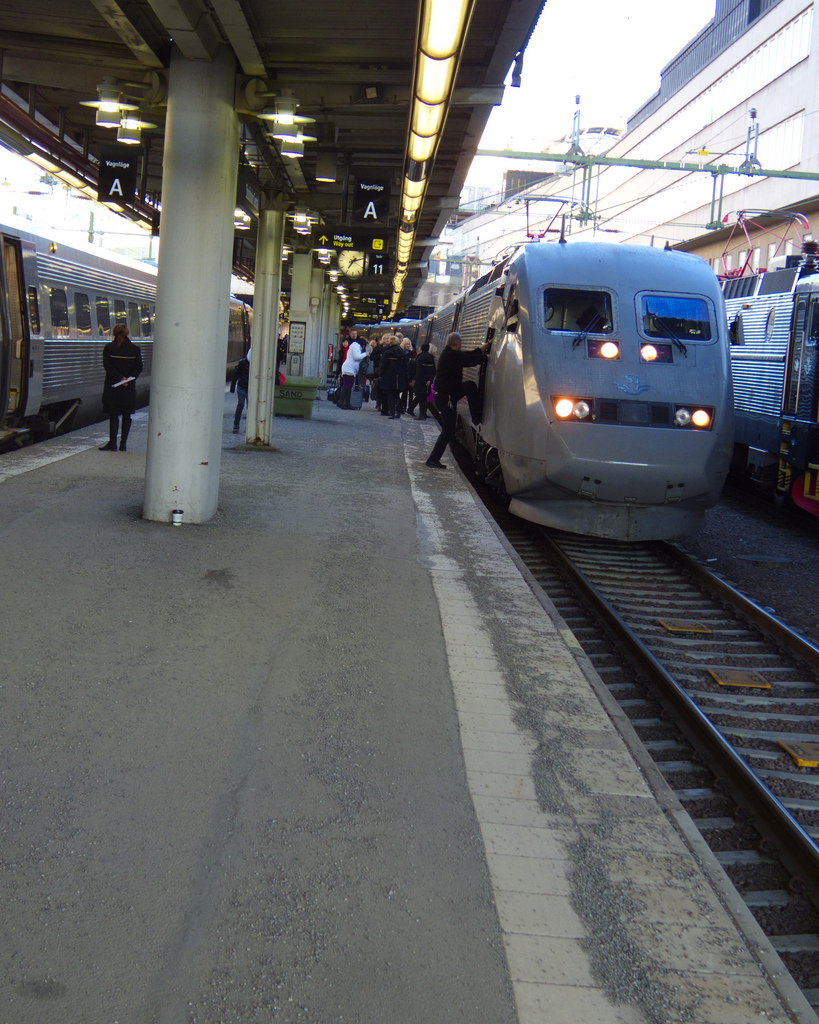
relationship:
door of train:
[462, 263, 526, 451] [2, 235, 362, 467]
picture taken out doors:
[67, 64, 720, 762] [492, 47, 752, 742]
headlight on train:
[599, 339, 619, 362] [346, 238, 737, 546]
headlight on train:
[643, 344, 657, 361] [346, 238, 737, 546]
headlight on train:
[556, 399, 573, 416] [346, 238, 737, 546]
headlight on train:
[574, 402, 590, 418] [346, 238, 737, 546]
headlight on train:
[675, 406, 689, 428] [346, 238, 737, 546]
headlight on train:
[695, 408, 709, 424] [346, 238, 737, 546]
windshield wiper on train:
[571, 290, 614, 349] [346, 238, 737, 546]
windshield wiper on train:
[643, 302, 693, 357] [346, 238, 737, 546]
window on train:
[538, 267, 619, 344] [346, 238, 737, 546]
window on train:
[640, 289, 714, 342] [346, 238, 737, 546]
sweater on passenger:
[342, 339, 371, 376] [333, 327, 370, 408]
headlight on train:
[592, 331, 626, 369] [346, 238, 737, 546]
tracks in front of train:
[525, 533, 816, 1018] [346, 238, 737, 546]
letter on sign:
[358, 198, 377, 226] [340, 164, 395, 239]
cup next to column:
[165, 506, 188, 531] [124, 61, 232, 527]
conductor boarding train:
[409, 314, 493, 475] [419, 232, 718, 550]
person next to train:
[103, 314, 149, 455] [6, 221, 254, 436]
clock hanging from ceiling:
[332, 247, 376, 278] [6, 68, 473, 343]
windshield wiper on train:
[571, 290, 622, 363] [402, 233, 738, 557]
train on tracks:
[387, 247, 723, 564] [521, 528, 793, 886]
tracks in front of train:
[527, 537, 793, 995] [365, 226, 719, 578]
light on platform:
[389, 162, 423, 316] [8, 1, 740, 915]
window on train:
[51, 278, 79, 336] [8, 221, 313, 456]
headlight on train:
[669, 401, 695, 429] [362, 235, 729, 561]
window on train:
[538, 285, 613, 344] [346, 238, 737, 546]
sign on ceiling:
[340, 174, 395, 230] [0, 0, 547, 328]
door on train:
[462, 263, 526, 451] [346, 238, 737, 546]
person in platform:
[90, 314, 150, 467] [15, 382, 737, 1014]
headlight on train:
[552, 394, 577, 420] [380, 262, 729, 544]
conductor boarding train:
[410, 330, 494, 469] [346, 238, 737, 546]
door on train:
[463, 327, 509, 450] [325, 236, 706, 541]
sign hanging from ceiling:
[340, 164, 395, 239] [12, 16, 542, 348]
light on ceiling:
[371, 2, 485, 340] [19, 4, 531, 391]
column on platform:
[123, 56, 247, 533] [12, 10, 683, 821]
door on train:
[5, 233, 37, 423] [6, 221, 254, 436]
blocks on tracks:
[651, 607, 779, 703] [527, 537, 793, 995]